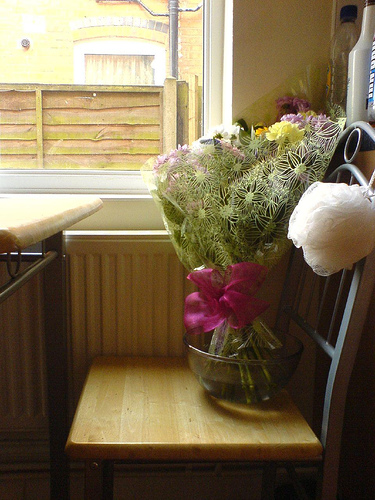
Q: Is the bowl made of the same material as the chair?
A: No, the bowl is made of glass and the chair is made of wood.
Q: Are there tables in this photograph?
A: Yes, there is a table.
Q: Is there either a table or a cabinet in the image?
A: Yes, there is a table.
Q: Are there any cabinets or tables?
A: Yes, there is a table.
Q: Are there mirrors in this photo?
A: No, there are no mirrors.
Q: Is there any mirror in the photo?
A: No, there are no mirrors.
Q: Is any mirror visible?
A: No, there are no mirrors.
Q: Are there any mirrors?
A: No, there are no mirrors.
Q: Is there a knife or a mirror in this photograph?
A: No, there are no mirrors or knives.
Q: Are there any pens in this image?
A: No, there are no pens.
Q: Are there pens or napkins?
A: No, there are no pens or napkins.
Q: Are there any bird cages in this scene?
A: No, there are no bird cages.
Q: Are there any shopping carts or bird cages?
A: No, there are no bird cages or shopping carts.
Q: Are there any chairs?
A: Yes, there is a chair.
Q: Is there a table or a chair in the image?
A: Yes, there is a chair.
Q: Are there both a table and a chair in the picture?
A: Yes, there are both a chair and a table.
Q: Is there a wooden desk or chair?
A: Yes, there is a wood chair.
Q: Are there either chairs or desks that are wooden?
A: Yes, the chair is wooden.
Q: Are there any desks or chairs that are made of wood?
A: Yes, the chair is made of wood.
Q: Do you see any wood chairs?
A: Yes, there is a wood chair.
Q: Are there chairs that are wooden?
A: Yes, there is a chair that is wooden.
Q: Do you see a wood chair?
A: Yes, there is a chair that is made of wood.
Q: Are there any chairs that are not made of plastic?
A: Yes, there is a chair that is made of wood.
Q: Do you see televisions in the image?
A: No, there are no televisions.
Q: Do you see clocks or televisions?
A: No, there are no televisions or clocks.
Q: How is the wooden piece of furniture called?
A: The piece of furniture is a chair.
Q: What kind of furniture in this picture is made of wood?
A: The furniture is a chair.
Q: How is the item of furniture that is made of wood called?
A: The piece of furniture is a chair.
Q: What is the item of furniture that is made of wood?
A: The piece of furniture is a chair.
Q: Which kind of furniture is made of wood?
A: The furniture is a chair.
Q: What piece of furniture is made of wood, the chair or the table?
A: The chair is made of wood.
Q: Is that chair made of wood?
A: Yes, the chair is made of wood.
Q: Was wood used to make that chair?
A: Yes, the chair is made of wood.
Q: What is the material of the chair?
A: The chair is made of wood.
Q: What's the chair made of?
A: The chair is made of wood.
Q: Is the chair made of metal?
A: No, the chair is made of wood.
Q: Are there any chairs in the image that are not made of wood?
A: No, there is a chair but it is made of wood.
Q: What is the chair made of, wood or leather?
A: The chair is made of wood.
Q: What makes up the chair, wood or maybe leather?
A: The chair is made of wood.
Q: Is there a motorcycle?
A: No, there are no motorcycles.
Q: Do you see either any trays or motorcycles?
A: No, there are no motorcycles or trays.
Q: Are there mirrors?
A: No, there are no mirrors.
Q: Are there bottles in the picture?
A: Yes, there is a bottle.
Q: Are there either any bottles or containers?
A: Yes, there is a bottle.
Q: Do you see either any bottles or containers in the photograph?
A: Yes, there is a bottle.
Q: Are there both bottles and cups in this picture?
A: No, there is a bottle but no cups.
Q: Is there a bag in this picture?
A: No, there are no bags.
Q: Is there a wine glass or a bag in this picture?
A: No, there are no bags or wine glasses.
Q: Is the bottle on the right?
A: Yes, the bottle is on the right of the image.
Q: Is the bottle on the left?
A: No, the bottle is on the right of the image.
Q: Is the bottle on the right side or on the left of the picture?
A: The bottle is on the right of the image.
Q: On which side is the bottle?
A: The bottle is on the right of the image.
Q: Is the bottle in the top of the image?
A: Yes, the bottle is in the top of the image.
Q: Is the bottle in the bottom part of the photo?
A: No, the bottle is in the top of the image.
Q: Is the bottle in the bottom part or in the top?
A: The bottle is in the top of the image.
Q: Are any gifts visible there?
A: No, there are no gifts.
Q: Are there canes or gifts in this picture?
A: No, there are no gifts or canes.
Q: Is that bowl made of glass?
A: Yes, the bowl is made of glass.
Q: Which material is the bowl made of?
A: The bowl is made of glass.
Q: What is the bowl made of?
A: The bowl is made of glass.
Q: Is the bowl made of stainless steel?
A: No, the bowl is made of glass.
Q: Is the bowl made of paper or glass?
A: The bowl is made of glass.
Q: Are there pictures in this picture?
A: No, there are no pictures.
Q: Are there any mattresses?
A: No, there are no mattresses.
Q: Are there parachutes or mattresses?
A: No, there are no mattresses or parachutes.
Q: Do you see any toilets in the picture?
A: No, there are no toilets.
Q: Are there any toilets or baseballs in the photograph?
A: No, there are no toilets or baseballs.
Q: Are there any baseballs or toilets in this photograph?
A: No, there are no toilets or baseballs.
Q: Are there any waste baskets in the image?
A: No, there are no waste baskets.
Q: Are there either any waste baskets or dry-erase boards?
A: No, there are no waste baskets or dry-erase boards.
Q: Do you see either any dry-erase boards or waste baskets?
A: No, there are no waste baskets or dry-erase boards.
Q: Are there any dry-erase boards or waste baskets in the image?
A: No, there are no waste baskets or dry-erase boards.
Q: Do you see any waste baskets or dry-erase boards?
A: No, there are no waste baskets or dry-erase boards.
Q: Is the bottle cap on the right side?
A: Yes, the bottle cap is on the right of the image.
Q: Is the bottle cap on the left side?
A: No, the bottle cap is on the right of the image.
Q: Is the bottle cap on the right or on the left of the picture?
A: The bottle cap is on the right of the image.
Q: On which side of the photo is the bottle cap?
A: The bottle cap is on the right of the image.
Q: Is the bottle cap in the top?
A: Yes, the bottle cap is in the top of the image.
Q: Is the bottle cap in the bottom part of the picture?
A: No, the bottle cap is in the top of the image.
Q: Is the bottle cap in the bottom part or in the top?
A: The bottle cap is in the top of the image.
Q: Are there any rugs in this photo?
A: No, there are no rugs.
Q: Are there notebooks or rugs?
A: No, there are no rugs or notebooks.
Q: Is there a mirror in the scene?
A: No, there are no mirrors.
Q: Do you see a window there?
A: Yes, there is a window.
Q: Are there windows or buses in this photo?
A: Yes, there is a window.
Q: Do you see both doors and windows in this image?
A: No, there is a window but no doors.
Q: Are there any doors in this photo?
A: No, there are no doors.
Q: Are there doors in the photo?
A: No, there are no doors.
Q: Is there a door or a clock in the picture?
A: No, there are no doors or clocks.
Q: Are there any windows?
A: Yes, there is a window.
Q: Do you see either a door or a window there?
A: Yes, there is a window.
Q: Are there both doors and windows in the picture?
A: No, there is a window but no doors.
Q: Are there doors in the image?
A: No, there are no doors.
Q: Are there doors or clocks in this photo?
A: No, there are no doors or clocks.